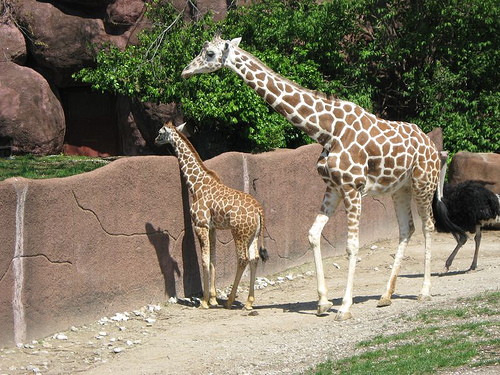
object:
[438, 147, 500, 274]
ostrich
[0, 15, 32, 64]
rocks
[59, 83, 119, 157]
opening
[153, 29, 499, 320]
animals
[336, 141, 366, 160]
spots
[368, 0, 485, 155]
trees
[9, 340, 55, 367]
gravel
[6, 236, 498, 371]
dirt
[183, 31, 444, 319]
giraffe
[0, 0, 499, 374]
zoo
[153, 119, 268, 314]
baby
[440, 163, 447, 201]
neck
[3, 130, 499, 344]
fence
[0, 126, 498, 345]
cement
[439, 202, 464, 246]
tuft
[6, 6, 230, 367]
left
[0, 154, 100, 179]
patch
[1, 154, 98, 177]
grass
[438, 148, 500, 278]
upright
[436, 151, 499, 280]
adult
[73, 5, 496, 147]
leafy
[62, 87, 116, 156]
red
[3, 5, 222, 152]
wall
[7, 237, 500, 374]
path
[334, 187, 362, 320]
legs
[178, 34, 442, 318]
adult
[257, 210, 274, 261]
tail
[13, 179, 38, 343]
stain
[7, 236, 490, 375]
ground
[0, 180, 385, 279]
crack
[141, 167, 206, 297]
shadow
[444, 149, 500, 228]
stone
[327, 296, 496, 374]
blade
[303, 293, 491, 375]
grass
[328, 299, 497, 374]
cluster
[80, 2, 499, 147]
cluster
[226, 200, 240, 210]
brown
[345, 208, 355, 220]
spot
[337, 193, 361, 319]
leg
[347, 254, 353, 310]
white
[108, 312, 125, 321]
white